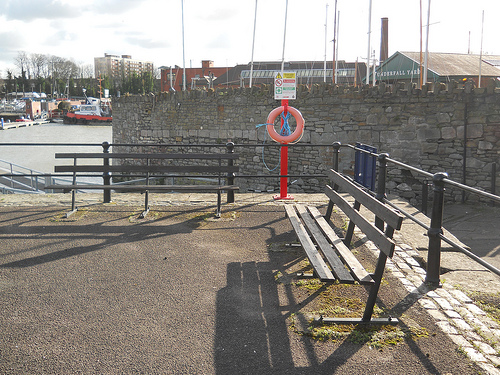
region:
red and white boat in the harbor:
[64, 104, 115, 121]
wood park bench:
[286, 170, 414, 294]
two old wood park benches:
[43, 152, 463, 272]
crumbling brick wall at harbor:
[111, 92, 497, 158]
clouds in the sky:
[18, 5, 173, 50]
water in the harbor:
[21, 120, 101, 149]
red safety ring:
[263, 104, 314, 138]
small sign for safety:
[270, 65, 300, 100]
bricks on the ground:
[384, 240, 494, 342]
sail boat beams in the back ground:
[163, 4, 486, 61]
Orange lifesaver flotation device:
[256, 106, 316, 149]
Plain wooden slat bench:
[276, 168, 407, 334]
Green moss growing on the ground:
[298, 300, 424, 354]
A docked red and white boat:
[60, 93, 109, 131]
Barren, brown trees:
[12, 50, 79, 88]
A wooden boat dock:
[3, 110, 50, 130]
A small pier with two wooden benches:
[57, 128, 475, 346]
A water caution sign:
[265, 64, 306, 105]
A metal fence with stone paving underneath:
[325, 133, 498, 356]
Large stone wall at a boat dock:
[108, 79, 490, 198]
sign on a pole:
[256, 55, 317, 190]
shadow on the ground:
[208, 239, 312, 374]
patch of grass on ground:
[310, 290, 359, 322]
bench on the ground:
[53, 140, 254, 213]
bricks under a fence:
[411, 281, 492, 363]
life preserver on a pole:
[260, 99, 310, 146]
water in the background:
[26, 125, 99, 152]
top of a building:
[368, 44, 495, 99]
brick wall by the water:
[115, 88, 485, 174]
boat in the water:
[61, 90, 105, 126]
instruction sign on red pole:
[272, 70, 297, 98]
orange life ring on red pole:
[265, 105, 305, 148]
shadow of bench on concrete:
[235, 258, 289, 367]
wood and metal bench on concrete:
[281, 167, 400, 329]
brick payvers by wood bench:
[388, 261, 421, 286]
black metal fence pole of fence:
[424, 171, 450, 283]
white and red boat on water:
[60, 103, 111, 125]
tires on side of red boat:
[64, 117, 86, 125]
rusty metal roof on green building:
[360, 52, 490, 74]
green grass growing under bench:
[312, 318, 404, 343]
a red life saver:
[263, 98, 309, 147]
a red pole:
[273, 102, 292, 188]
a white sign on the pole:
[271, 68, 292, 98]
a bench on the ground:
[283, 168, 390, 332]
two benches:
[35, 134, 435, 321]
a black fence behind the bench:
[7, 131, 337, 192]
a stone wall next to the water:
[111, 88, 489, 184]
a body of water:
[0, 122, 113, 176]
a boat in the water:
[63, 84, 126, 128]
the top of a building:
[378, 47, 490, 83]